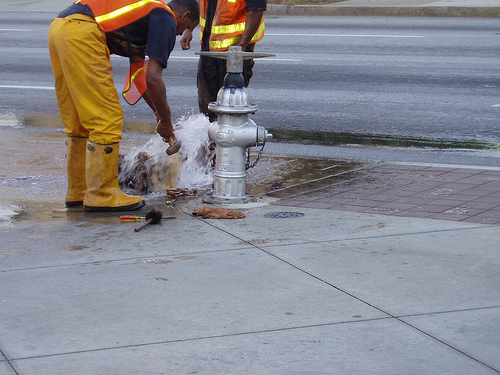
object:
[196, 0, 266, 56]
vest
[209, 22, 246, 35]
stripes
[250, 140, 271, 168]
chain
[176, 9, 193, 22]
ear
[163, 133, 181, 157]
tool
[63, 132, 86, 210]
boot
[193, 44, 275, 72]
handle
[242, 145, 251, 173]
chains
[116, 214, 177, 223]
screwdriver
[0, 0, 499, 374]
ground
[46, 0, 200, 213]
man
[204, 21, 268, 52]
stripes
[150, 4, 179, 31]
shoulder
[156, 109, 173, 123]
wrist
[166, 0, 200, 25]
hair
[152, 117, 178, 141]
hand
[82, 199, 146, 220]
soles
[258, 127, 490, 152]
puddle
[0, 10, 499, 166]
road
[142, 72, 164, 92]
elbow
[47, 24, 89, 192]
leg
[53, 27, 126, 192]
leg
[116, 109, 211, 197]
water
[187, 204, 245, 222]
glove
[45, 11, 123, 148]
pants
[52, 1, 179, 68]
shirt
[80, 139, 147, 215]
boots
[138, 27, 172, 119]
arm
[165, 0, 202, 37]
head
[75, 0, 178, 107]
outfit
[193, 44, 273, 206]
fire hydrant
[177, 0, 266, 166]
man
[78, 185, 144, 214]
feet